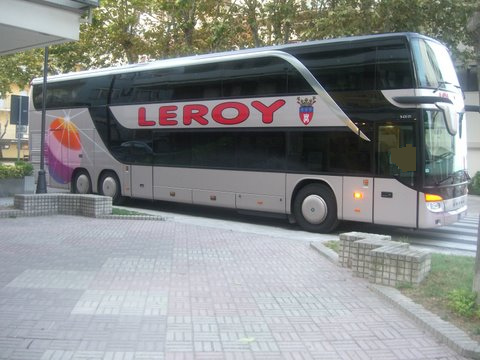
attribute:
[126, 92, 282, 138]
letters — red, Large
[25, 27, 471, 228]
bus — silver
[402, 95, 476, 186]
windshield — large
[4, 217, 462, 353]
sidewalk — decorative, bricked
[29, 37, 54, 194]
pole — metal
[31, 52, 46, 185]
post — street light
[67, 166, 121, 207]
wheels — back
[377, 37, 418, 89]
window — black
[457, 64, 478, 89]
window — black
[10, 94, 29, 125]
window — black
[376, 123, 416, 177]
window — black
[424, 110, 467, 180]
window — black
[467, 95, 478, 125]
building — beige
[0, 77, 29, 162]
building — beige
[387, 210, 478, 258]
crosswalk — white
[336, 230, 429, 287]
block — bricked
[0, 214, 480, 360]
sidewalk — brick patterned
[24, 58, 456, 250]
bus — pictured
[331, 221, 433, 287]
bricks — decorative, stacked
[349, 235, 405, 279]
block — bricks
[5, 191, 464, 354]
sidewalk — brick, white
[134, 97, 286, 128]
name — Leroy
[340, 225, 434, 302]
seating area — concrete